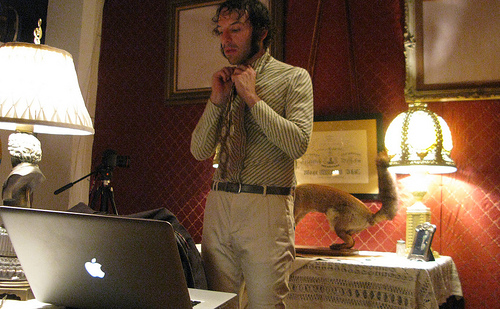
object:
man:
[187, 0, 315, 309]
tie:
[215, 82, 247, 184]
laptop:
[0, 204, 240, 309]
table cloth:
[281, 244, 465, 309]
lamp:
[381, 102, 458, 176]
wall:
[87, 0, 500, 309]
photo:
[161, 0, 282, 106]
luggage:
[164, 218, 209, 290]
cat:
[290, 150, 399, 249]